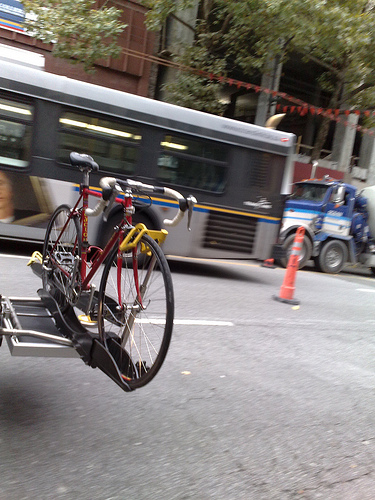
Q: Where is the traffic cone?
A: In the road.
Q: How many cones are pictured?
A: One.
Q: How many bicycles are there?
A: One.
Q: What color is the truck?
A: Blue.